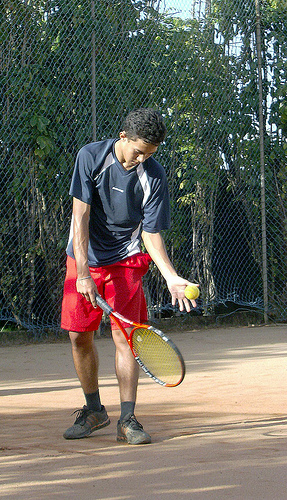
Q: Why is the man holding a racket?
A: To hit the ball.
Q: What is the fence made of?
A: Metal chin link.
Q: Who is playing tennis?
A: The man.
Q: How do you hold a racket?
A: With your hand.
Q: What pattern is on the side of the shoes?
A: Stripes.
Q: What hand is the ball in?
A: The left.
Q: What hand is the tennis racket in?
A: The right.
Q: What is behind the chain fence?
A: Trees.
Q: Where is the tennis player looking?
A: Down.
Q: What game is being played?
A: Tennis.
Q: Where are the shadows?
A: On the ground.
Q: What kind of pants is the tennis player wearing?
A: Shorts.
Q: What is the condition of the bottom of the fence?
A: Torn.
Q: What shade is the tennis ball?
A: Bright yellow.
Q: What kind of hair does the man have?
A: Curly.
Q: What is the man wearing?
A: A black shirt.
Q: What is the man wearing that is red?
A: Shorts.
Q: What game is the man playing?
A: Tennis.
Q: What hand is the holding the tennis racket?
A: The right one.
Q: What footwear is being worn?
A: Sneakers.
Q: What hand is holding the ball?
A: The right.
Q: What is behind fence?
A: Trees.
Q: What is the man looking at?
A: Tennis ball.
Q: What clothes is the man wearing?
A: Blue shirt and red shorts.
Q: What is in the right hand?
A: Tennis racket.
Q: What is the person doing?
A: Playing tennis.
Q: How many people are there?
A: One.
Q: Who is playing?
A: A boy.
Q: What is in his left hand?
A: A ball.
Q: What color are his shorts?
A: Red.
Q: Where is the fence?
A: Behind boy.